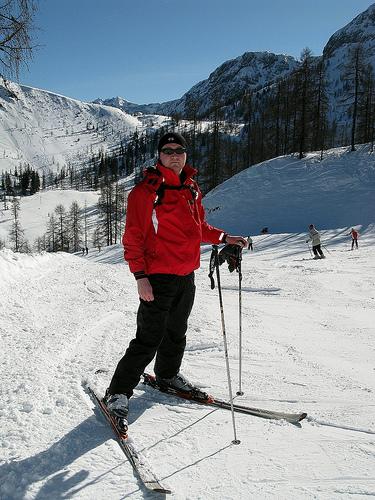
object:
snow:
[250, 189, 292, 251]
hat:
[158, 132, 189, 156]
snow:
[348, 337, 375, 374]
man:
[306, 224, 326, 260]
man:
[346, 227, 358, 249]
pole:
[215, 247, 237, 442]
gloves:
[215, 244, 243, 273]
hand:
[225, 235, 248, 247]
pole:
[239, 247, 243, 392]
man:
[104, 132, 248, 419]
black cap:
[158, 133, 189, 158]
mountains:
[173, 50, 266, 129]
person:
[261, 227, 269, 234]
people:
[246, 235, 253, 251]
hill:
[0, 227, 70, 318]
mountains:
[0, 77, 147, 229]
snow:
[317, 453, 361, 499]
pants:
[108, 270, 195, 399]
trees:
[3, 158, 39, 196]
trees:
[96, 176, 127, 248]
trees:
[73, 145, 94, 183]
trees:
[204, 87, 233, 183]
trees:
[135, 117, 156, 162]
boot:
[154, 335, 194, 391]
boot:
[101, 359, 143, 421]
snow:
[285, 265, 350, 296]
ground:
[7, 240, 20, 264]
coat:
[122, 157, 229, 280]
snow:
[3, 325, 89, 425]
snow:
[0, 83, 41, 144]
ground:
[332, 385, 373, 497]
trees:
[62, 189, 108, 251]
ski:
[142, 373, 307, 425]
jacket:
[349, 230, 360, 240]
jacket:
[306, 227, 321, 246]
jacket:
[247, 238, 253, 244]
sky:
[29, 10, 139, 66]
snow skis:
[87, 386, 172, 494]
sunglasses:
[160, 147, 187, 155]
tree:
[348, 55, 375, 151]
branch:
[0, 0, 47, 74]